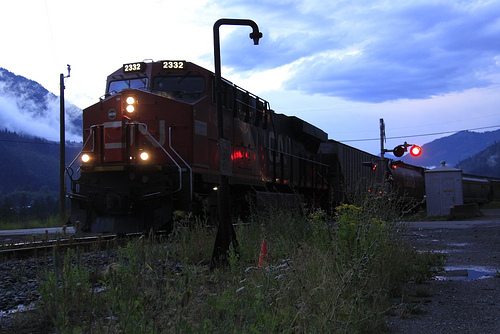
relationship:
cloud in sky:
[203, 0, 500, 104] [324, 58, 404, 98]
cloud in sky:
[203, 0, 500, 104] [82, 9, 150, 33]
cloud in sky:
[203, 0, 500, 104] [2, 4, 496, 156]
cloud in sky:
[289, 50, 479, 100] [2, 4, 496, 156]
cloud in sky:
[203, 0, 500, 104] [284, 14, 484, 130]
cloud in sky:
[203, 0, 500, 104] [53, 0, 436, 105]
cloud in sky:
[203, 0, 500, 104] [232, 24, 483, 149]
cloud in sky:
[203, 0, 500, 104] [42, 0, 480, 102]